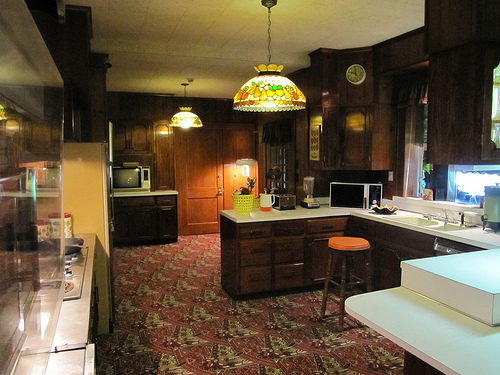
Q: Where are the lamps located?
A: Ceiling.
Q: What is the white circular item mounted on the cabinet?
A: Clock.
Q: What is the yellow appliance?
A: Refrigerator.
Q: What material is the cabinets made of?
A: Wood.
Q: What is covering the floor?
A: Carpet.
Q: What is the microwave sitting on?
A: Counter.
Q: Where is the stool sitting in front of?
A: Sink.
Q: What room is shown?
A: Kitchen.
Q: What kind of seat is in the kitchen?
A: Stool.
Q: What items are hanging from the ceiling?
A: Lamps.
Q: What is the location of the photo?
A: Kitchen.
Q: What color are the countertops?
A: White.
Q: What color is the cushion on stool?
A: Orange.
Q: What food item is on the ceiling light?
A: Fruits.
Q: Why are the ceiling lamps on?
A: To provide light.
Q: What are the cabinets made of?
A: Wood.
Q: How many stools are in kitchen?
A: 1.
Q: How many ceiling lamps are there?
A: 2.